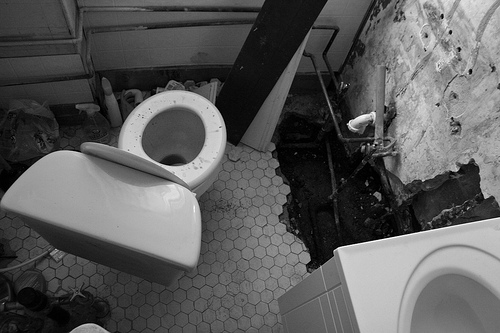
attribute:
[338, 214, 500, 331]
sink — clean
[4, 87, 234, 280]
toilet — white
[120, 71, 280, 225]
toilet — white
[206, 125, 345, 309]
floor — crooked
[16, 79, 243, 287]
toilet — white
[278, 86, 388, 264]
torn tile — torn out